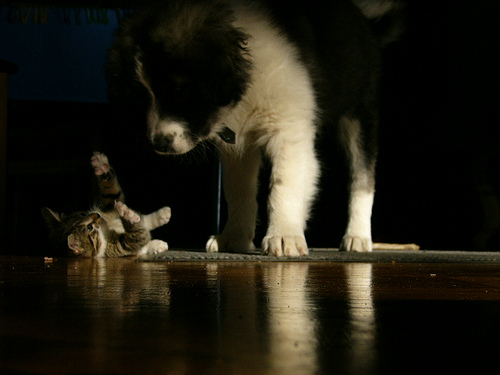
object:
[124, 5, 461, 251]
dog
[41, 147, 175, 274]
kitten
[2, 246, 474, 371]
ground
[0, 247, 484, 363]
floors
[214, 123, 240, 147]
collar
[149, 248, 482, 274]
rug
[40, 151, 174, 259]
cat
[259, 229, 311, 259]
paw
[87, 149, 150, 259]
legs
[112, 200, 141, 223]
claw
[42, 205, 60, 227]
ear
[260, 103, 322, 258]
leg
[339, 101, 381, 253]
leg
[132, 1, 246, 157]
head